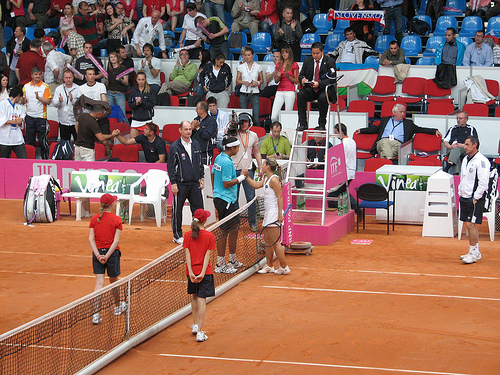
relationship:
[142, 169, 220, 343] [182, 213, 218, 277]
woman wears shirt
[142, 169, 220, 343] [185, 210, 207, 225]
woman wears hat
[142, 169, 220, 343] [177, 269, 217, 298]
woman wears shorts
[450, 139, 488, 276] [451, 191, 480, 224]
man wears shorts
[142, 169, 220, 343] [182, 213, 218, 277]
woman wearing shirt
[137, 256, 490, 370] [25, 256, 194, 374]
court has net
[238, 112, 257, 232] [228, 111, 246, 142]
man holds camera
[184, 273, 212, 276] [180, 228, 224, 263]
hands behind back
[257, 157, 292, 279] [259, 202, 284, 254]
woman holds racket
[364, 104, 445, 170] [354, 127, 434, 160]
man relaxes in chair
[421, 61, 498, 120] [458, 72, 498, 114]
clothing on chair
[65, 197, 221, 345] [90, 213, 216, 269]
girls wear shirts